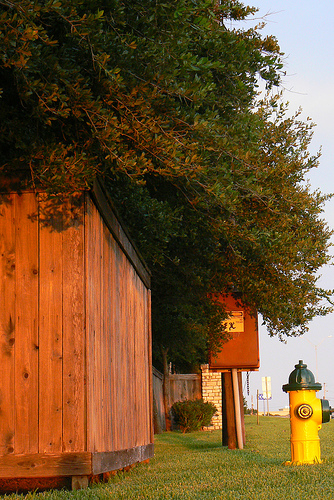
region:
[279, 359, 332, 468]
a green and yellow fire hydrant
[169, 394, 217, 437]
a short bush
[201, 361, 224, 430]
a brick pillar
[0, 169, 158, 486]
a tall wooden fence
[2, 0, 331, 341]
a large leafy tree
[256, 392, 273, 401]
a blue sign in the distance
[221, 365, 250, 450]
a wooden post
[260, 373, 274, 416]
the back of a street sign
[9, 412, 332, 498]
lush green grass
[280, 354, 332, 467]
a fire hydrant in the grass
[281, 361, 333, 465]
the fire hydrant is yellow and green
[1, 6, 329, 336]
the tree overhangs over the fence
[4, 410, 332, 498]
the grass is well mowed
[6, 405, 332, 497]
the grass is green in color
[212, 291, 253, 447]
a wooden pole is planted on the ground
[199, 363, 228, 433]
a stone column is seen in the bacground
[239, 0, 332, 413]
the sky is light blue in color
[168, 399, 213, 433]
a bush is seen in the back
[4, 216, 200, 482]
the fence is made of wood panels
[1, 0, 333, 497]
the photo was taken outdoors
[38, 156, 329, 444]
The sun is setting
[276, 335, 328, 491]
This is a fire hydrant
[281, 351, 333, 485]
The hydrant is yellow and green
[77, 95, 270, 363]
The tree is covering the building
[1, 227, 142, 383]
The boards are vertical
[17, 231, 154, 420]
The building is brown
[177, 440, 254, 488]
The grass is green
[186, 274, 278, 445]
This is a power box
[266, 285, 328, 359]
The sky is blue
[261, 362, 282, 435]
There are signs in the background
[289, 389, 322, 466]
Yellow part of fire hydrant.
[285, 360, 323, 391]
Green top of fire hydrant.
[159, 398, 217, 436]
Green bush by brick structure.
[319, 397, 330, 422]
Green frontal structure on fire hydrant.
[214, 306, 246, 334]
Yellow warning sticker on metal sign.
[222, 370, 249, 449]
Wooden post holding up brown metal sign next to the fire hydrant.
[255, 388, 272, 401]
Blue and white billboard in the background.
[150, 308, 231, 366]
Tree above wooden fence and small bush.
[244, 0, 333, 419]
Visible clouds in the background.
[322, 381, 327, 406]
Electrical pole in right side of photo.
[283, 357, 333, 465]
the fire hydrant is yellow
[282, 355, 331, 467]
the top of the hydrant is green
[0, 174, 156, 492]
the building is wooden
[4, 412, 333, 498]
the grass is green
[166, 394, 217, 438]
the bush is green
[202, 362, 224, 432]
the building is brick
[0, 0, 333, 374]
the tree is green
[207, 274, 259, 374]
the electrical box is rusted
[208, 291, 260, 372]
the electrical box is red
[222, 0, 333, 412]
the sky is blue